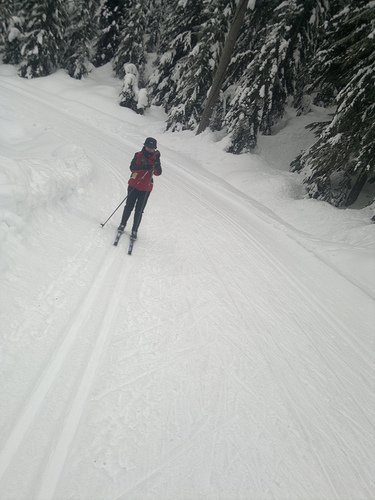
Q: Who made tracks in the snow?
A: Skiers.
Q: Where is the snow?
A: On the slope.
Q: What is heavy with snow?
A: Trees.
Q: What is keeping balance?
A: Ski poles.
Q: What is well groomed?
A: Ski trail.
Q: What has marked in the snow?
A: Ski tracks.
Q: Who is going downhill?
A: A woman.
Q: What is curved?
A: Ski trail.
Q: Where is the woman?
A: On the trail.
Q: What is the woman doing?
A: Skiing.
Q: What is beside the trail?
A: Trees.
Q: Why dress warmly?
A: It is cold.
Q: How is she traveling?
A: On skis.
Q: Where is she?
A: On a snow trail.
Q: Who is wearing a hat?
A: The skier.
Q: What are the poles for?
A: For balance and to push.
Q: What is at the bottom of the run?
A: A ski lift.